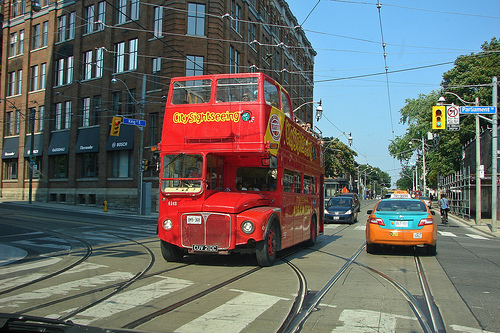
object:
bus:
[158, 69, 326, 262]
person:
[439, 193, 450, 226]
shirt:
[439, 196, 449, 210]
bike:
[441, 209, 449, 226]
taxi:
[366, 198, 437, 252]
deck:
[165, 75, 326, 171]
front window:
[161, 153, 204, 194]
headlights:
[242, 220, 254, 236]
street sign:
[459, 105, 497, 115]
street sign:
[120, 115, 149, 129]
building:
[1, 1, 159, 214]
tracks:
[415, 253, 447, 331]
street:
[2, 258, 451, 332]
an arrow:
[447, 105, 461, 119]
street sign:
[447, 106, 461, 128]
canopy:
[48, 130, 71, 156]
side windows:
[282, 171, 315, 199]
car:
[324, 194, 357, 222]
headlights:
[346, 207, 352, 215]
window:
[329, 196, 352, 207]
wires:
[376, 2, 398, 134]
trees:
[411, 38, 499, 198]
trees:
[321, 135, 392, 198]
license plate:
[393, 220, 409, 228]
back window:
[378, 198, 426, 212]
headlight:
[164, 218, 173, 231]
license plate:
[193, 244, 219, 252]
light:
[433, 107, 447, 130]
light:
[110, 114, 122, 139]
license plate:
[187, 214, 203, 226]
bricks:
[164, 0, 187, 75]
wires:
[46, 1, 454, 72]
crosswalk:
[1, 258, 500, 332]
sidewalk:
[1, 196, 158, 221]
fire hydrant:
[102, 196, 109, 212]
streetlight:
[110, 70, 148, 220]